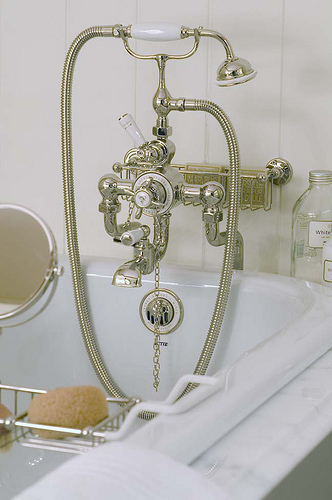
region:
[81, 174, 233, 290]
Tap is golden color.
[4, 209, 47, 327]
Mirror is in left side.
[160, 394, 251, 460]
Tub is white color.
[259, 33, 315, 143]
Wall is white color.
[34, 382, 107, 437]
Sponge is brown color.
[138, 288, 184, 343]
Symbol is white and blue color.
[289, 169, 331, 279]
Bottle is in the corner of the tub.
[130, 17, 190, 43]
Handle of shower is white color.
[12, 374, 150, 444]
Stand is silver and white color.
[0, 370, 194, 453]
Stand is fixed to the tub.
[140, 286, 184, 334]
Drain switch in a bathtub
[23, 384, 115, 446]
Loofah for washing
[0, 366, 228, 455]
Accessory tray on a bathtub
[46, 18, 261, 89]
Handheld spigot for a bathtub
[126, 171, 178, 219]
Water valve for a bathtub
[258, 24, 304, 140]
Tiled bathroom wall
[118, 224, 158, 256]
Switch for handheld spigot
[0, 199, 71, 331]
Vanity mirror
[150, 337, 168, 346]
Manufacturer logo on bathtub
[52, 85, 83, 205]
Flexible water line for handheld spigot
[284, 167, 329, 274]
jar with white label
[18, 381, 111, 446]
sponge in metal tray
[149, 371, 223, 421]
white handle on tub edge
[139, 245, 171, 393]
metal chain hanging from faucet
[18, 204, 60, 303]
edge of round mirror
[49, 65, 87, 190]
hose of shower head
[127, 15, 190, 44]
white handle of shower head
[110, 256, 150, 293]
chrome faucet of tub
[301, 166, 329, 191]
silver cap on bottle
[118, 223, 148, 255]
white handle on faucet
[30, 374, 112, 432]
Small round sponge in metal rack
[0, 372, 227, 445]
Metal rack attached to bath tub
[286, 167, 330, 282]
Clear bottle next to faucet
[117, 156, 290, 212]
Metal rack attached to wall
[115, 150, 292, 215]
Metal rack behind faucet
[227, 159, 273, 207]
Soap in metal rack attached to wall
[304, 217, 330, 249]
Tag on clear glass bottle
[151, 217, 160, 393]
Long chain dangling from faucet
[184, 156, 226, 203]
Soap bar next to soap bar in metal rack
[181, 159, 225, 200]
Soap bar is small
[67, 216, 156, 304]
the faucet is silver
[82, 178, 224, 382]
the faucet is silver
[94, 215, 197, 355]
the faucet is silver